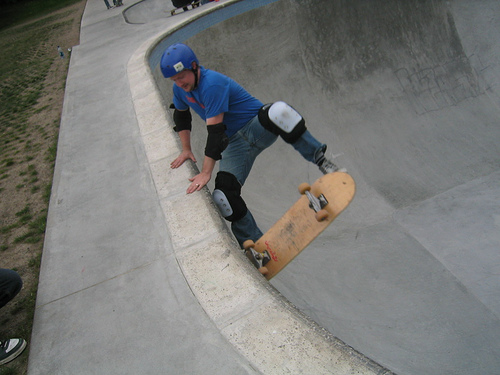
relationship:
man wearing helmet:
[161, 43, 348, 248] [152, 41, 202, 81]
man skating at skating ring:
[161, 43, 348, 248] [62, 18, 498, 346]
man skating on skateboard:
[161, 43, 348, 248] [243, 170, 355, 281]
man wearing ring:
[161, 43, 348, 248] [195, 184, 198, 187]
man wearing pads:
[161, 43, 348, 248] [269, 100, 297, 130]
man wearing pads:
[161, 43, 348, 248] [210, 186, 236, 221]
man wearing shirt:
[161, 43, 348, 248] [168, 67, 266, 140]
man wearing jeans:
[161, 43, 348, 248] [216, 103, 339, 245]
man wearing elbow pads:
[161, 43, 348, 248] [202, 120, 230, 162]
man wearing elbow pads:
[161, 43, 348, 248] [169, 102, 193, 132]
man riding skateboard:
[161, 43, 348, 248] [243, 170, 354, 279]